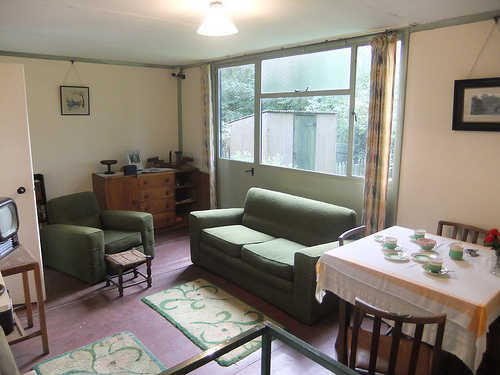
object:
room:
[0, 0, 500, 375]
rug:
[32, 330, 165, 374]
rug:
[139, 277, 286, 366]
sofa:
[187, 184, 356, 326]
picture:
[59, 85, 91, 117]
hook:
[70, 60, 74, 64]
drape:
[364, 29, 395, 233]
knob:
[19, 188, 26, 193]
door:
[0, 63, 49, 306]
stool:
[104, 250, 153, 295]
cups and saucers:
[379, 235, 402, 252]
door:
[294, 114, 317, 172]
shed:
[230, 108, 336, 173]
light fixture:
[197, 0, 238, 37]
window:
[216, 63, 256, 163]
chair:
[42, 191, 153, 283]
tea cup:
[428, 256, 444, 272]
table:
[315, 226, 499, 373]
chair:
[343, 298, 446, 375]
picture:
[452, 79, 498, 130]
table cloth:
[316, 228, 498, 375]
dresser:
[95, 171, 174, 225]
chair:
[436, 217, 492, 242]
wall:
[398, 11, 500, 244]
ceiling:
[0, 0, 499, 67]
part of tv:
[0, 197, 21, 258]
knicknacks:
[100, 148, 165, 176]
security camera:
[170, 67, 181, 77]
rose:
[485, 235, 494, 246]